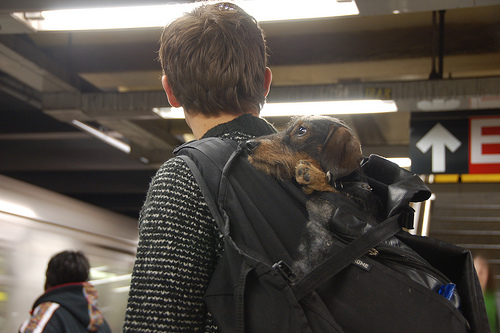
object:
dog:
[247, 113, 360, 192]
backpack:
[183, 141, 491, 332]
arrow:
[417, 123, 462, 172]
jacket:
[34, 284, 98, 332]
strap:
[292, 215, 411, 303]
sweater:
[123, 113, 298, 332]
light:
[10, 0, 361, 33]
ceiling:
[0, 6, 499, 176]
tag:
[413, 269, 459, 307]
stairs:
[425, 189, 500, 281]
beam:
[68, 80, 500, 120]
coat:
[32, 286, 110, 333]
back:
[203, 130, 371, 286]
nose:
[244, 134, 265, 151]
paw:
[293, 159, 325, 197]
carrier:
[270, 165, 414, 296]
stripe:
[429, 180, 500, 283]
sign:
[407, 101, 500, 184]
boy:
[116, 2, 488, 332]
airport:
[0, 0, 499, 332]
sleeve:
[122, 154, 223, 332]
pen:
[439, 283, 458, 314]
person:
[19, 248, 111, 333]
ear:
[319, 122, 354, 175]